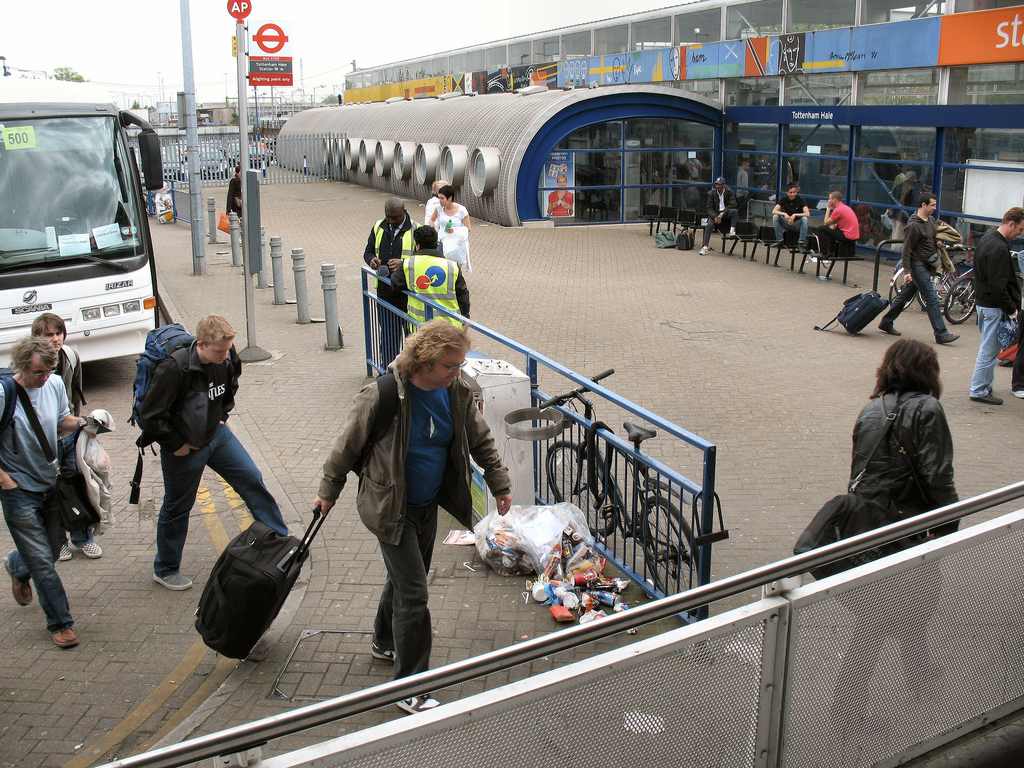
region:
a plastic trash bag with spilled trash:
[441, 497, 631, 628]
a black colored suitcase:
[195, 508, 328, 660]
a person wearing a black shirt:
[129, 313, 288, 596]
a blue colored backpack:
[129, 319, 196, 428]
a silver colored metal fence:
[357, 263, 715, 618]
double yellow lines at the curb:
[46, 462, 262, 766]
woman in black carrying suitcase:
[797, 333, 963, 751]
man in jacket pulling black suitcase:
[182, 314, 503, 722]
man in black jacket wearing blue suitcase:
[119, 309, 298, 595]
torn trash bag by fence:
[475, 374, 681, 640]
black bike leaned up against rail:
[538, 364, 725, 611]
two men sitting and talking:
[763, 184, 863, 277]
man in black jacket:
[696, 172, 744, 256]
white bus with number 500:
[2, 83, 174, 377]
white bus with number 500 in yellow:
[1, 71, 63, 154]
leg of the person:
[393, 613, 433, 652]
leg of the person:
[228, 480, 276, 529]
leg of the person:
[160, 489, 215, 522]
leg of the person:
[17, 537, 37, 573]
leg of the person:
[43, 495, 76, 528]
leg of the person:
[92, 496, 102, 525]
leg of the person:
[871, 298, 913, 314]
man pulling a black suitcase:
[190, 313, 516, 718]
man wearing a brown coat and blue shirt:
[309, 318, 516, 715]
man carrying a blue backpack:
[126, 312, 294, 591]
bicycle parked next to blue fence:
[357, 269, 727, 637]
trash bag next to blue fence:
[351, 265, 724, 642]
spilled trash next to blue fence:
[354, 262, 727, 642]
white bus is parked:
[0, 78, 168, 372]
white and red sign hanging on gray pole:
[231, 6, 298, 367]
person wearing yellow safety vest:
[389, 225, 475, 336]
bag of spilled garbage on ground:
[450, 506, 635, 623]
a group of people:
[0, 123, 1022, 706]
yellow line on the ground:
[75, 593, 240, 743]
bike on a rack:
[515, 361, 724, 606]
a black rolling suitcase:
[162, 461, 374, 662]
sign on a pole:
[216, 0, 268, 375]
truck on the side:
[0, 60, 177, 374]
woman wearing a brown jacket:
[320, 347, 527, 579]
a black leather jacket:
[837, 373, 965, 536]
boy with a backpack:
[107, 306, 305, 545]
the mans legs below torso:
[134, 432, 294, 565]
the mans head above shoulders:
[188, 312, 239, 367]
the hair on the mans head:
[393, 310, 469, 369]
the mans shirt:
[310, 366, 495, 531]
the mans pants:
[358, 509, 475, 691]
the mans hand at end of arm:
[487, 477, 519, 522]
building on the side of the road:
[272, 26, 1022, 277]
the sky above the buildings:
[16, 6, 590, 101]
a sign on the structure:
[244, 13, 295, 96]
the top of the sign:
[245, 16, 297, 59]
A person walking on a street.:
[0, 337, 110, 657]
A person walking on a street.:
[29, 311, 105, 564]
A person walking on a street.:
[133, 314, 289, 594]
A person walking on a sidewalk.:
[313, 314, 513, 713]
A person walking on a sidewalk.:
[789, 336, 963, 729]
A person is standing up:
[967, 204, 1022, 408]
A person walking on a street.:
[878, 193, 961, 343]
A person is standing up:
[426, 188, 472, 324]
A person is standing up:
[367, 200, 419, 375]